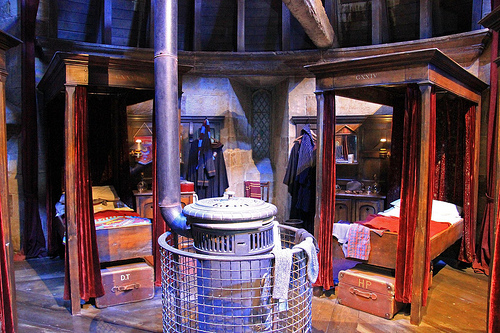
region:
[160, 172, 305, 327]
Small gas room heater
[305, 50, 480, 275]
Wooden canopy post bed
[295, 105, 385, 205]
Vanity station with mirror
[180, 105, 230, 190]
Dark wooden coat rack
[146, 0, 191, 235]
Long metal heat pipe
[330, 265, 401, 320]
Wooden personalized under bed drawer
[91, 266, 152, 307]
Etched under bed wooden drawer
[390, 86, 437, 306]
Red privacy bed curtain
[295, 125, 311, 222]
Blue bath robe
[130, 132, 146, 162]
Wall candle lamp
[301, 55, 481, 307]
The bed has a red blanket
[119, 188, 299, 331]
A wood burning stove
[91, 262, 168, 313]
The trunk has the initials D.T.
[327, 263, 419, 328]
The trunk has the initials HP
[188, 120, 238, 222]
There is a dark robe hanging by the bed to the left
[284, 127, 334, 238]
There is a dark robe hanging by the bed to the right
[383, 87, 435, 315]
The curtains are red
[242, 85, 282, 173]
There is one window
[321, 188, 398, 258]
The cabinet is wooden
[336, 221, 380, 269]
The fabric is red and blue checkered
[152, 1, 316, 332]
a wood stove used for heating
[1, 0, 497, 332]
an open loft type bedroom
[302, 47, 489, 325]
a wood canopy single bed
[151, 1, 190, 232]
the smoke stack for the stove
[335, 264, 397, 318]
luggage with the initials HP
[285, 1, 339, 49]
exposed wood beam of the loft space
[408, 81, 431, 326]
the wooden column of the canopy bed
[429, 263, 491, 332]
light wood floors of the loft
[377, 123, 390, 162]
a oil lamp mounted on the wall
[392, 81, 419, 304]
red velvet type material canopy bed curtain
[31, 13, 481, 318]
Harry Potter's sleeping chamber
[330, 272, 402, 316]
Harry Potter's trunk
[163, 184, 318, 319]
heating mechanism in room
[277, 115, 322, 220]
black wizard robes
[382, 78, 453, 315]
red bed curtains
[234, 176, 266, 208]
red and gold Griffindor scarf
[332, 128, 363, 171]
small mirror hung on wall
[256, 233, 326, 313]
socks drying near heater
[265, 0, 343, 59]
wooden beams in room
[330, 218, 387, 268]
pajamas hung over foot board of bed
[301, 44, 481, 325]
a large wooden covering for a bed.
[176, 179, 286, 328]
a trash can with a metal lid.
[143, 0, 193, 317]
a large wooden support pole.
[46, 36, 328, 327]
a large wooden bed structure.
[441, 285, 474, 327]
a section of a wooden floor.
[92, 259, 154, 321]
a piece of luggage.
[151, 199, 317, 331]
a metal basket around a trash can.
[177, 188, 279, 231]
a trash can lid.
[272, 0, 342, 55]
a large wooden support beam.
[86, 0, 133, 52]
a wooden support beam.